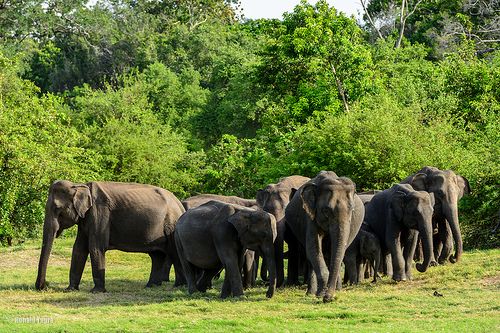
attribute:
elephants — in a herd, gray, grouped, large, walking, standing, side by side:
[35, 165, 472, 304]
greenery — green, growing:
[0, 0, 499, 246]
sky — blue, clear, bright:
[228, 0, 372, 27]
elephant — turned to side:
[36, 178, 187, 293]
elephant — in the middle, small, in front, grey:
[174, 200, 277, 299]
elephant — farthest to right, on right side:
[400, 166, 472, 264]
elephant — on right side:
[363, 182, 436, 283]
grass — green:
[1, 234, 499, 332]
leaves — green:
[0, 1, 499, 252]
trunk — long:
[34, 224, 59, 291]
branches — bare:
[359, 1, 424, 49]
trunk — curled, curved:
[441, 200, 464, 264]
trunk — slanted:
[324, 212, 351, 303]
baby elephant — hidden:
[344, 221, 383, 285]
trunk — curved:
[416, 219, 433, 273]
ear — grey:
[71, 183, 94, 219]